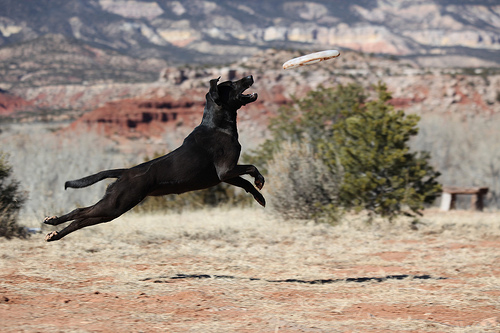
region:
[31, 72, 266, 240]
a leaping black dog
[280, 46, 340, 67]
a frisbee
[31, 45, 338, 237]
a black dog jumping to catch a frisbee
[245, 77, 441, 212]
a large green bush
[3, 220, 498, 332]
parched looking ground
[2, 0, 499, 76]
a gray looking hillside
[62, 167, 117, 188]
a dog's tail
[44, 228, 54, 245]
a dog's paw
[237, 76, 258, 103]
the open mouth of a dog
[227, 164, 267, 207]
the front legs of a black dog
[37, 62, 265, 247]
A black dog jumps to catch a frisbee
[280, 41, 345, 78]
white and brown flying frisbee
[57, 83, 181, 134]
red rocks in background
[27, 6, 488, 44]
mountains in far background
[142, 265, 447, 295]
long dark shadow cast on ground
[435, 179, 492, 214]
wooden bench in near background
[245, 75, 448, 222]
large green bush behind dog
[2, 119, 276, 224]
row of shrubbery behind dog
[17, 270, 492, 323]
dead grass on ground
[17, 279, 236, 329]
red dirt in foreground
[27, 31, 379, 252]
Black color dog with frisbee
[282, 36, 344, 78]
White color frisbee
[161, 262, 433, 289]
Shadow of the dog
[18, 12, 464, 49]
Big size mountain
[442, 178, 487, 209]
Stone bench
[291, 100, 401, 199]
Tree with leaves and branches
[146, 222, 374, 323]
Dirt with grass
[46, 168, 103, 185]
Tail of the dog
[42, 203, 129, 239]
Legs of the dog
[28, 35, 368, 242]
Black color dog ready to catch the frisbee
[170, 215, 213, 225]
this is the ground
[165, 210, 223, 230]
the ground has grass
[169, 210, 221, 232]
the grass is green in color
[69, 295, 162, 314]
the area is arid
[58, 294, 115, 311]
the sand is brown in color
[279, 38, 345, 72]
this is a frisbey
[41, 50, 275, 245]
this is a dog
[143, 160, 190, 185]
the fur is black in color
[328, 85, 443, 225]
this is a tree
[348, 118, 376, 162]
the leaves are green in color